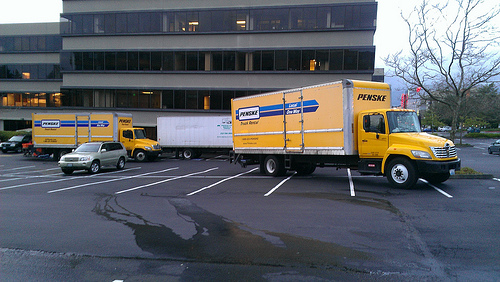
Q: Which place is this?
A: It is a parking lot.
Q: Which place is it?
A: It is a parking lot.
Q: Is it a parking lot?
A: Yes, it is a parking lot.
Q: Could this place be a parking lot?
A: Yes, it is a parking lot.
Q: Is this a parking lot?
A: Yes, it is a parking lot.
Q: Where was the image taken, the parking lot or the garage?
A: It was taken at the parking lot.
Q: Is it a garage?
A: No, it is a parking lot.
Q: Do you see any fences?
A: No, there are no fences.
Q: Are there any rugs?
A: No, there are no rugs.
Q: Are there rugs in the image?
A: No, there are no rugs.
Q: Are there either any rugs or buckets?
A: No, there are no rugs or buckets.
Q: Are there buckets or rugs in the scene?
A: No, there are no rugs or buckets.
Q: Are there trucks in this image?
A: Yes, there is a truck.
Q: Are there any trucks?
A: Yes, there is a truck.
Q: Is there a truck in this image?
A: Yes, there is a truck.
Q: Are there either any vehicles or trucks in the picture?
A: Yes, there is a truck.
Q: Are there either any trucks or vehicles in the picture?
A: Yes, there is a truck.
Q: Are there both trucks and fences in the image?
A: No, there is a truck but no fences.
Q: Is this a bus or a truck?
A: This is a truck.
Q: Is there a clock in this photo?
A: No, there are no clocks.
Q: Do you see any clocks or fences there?
A: No, there are no clocks or fences.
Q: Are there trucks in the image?
A: Yes, there is a truck.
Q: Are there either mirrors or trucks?
A: Yes, there is a truck.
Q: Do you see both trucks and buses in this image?
A: No, there is a truck but no buses.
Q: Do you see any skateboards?
A: No, there are no skateboards.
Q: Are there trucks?
A: Yes, there is a truck.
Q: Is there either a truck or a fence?
A: Yes, there is a truck.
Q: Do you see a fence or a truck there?
A: Yes, there is a truck.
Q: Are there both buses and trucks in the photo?
A: No, there is a truck but no buses.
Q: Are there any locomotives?
A: No, there are no locomotives.